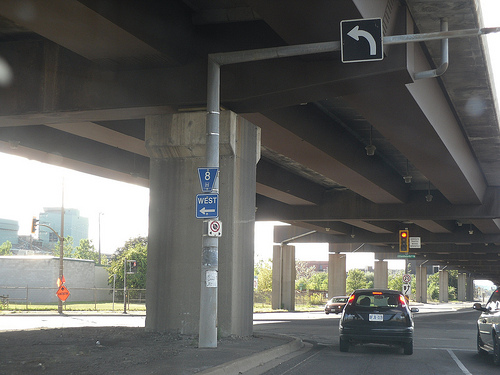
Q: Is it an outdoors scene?
A: Yes, it is outdoors.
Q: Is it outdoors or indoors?
A: It is outdoors.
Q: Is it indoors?
A: No, it is outdoors.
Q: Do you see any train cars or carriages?
A: No, there are no train cars or carriages.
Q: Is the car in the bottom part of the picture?
A: Yes, the car is in the bottom of the image.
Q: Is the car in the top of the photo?
A: No, the car is in the bottom of the image.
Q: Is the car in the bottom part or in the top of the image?
A: The car is in the bottom of the image.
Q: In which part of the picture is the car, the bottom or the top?
A: The car is in the bottom of the image.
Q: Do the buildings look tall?
A: Yes, the buildings are tall.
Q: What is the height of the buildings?
A: The buildings are tall.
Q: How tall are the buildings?
A: The buildings are tall.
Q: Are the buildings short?
A: No, the buildings are tall.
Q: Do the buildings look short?
A: No, the buildings are tall.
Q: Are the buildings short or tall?
A: The buildings are tall.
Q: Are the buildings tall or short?
A: The buildings are tall.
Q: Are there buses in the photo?
A: No, there are no buses.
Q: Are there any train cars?
A: No, there are no train cars.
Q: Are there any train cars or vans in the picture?
A: No, there are no train cars or vans.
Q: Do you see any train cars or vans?
A: No, there are no train cars or vans.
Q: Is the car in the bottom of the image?
A: Yes, the car is in the bottom of the image.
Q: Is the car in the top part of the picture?
A: No, the car is in the bottom of the image.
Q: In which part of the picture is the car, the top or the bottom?
A: The car is in the bottom of the image.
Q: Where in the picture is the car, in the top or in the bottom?
A: The car is in the bottom of the image.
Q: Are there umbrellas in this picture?
A: No, there are no umbrellas.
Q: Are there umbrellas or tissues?
A: No, there are no umbrellas or tissues.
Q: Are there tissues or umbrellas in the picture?
A: No, there are no umbrellas or tissues.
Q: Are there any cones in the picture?
A: No, there are no cones.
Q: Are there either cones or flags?
A: No, there are no cones or flags.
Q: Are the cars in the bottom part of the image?
A: Yes, the cars are in the bottom of the image.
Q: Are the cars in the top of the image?
A: No, the cars are in the bottom of the image.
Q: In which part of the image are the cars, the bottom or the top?
A: The cars are in the bottom of the image.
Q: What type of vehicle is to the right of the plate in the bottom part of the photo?
A: The vehicles are cars.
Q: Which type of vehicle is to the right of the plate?
A: The vehicles are cars.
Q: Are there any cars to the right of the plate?
A: Yes, there are cars to the right of the plate.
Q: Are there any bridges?
A: Yes, there is a bridge.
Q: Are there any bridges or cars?
A: Yes, there is a bridge.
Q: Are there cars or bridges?
A: Yes, there is a bridge.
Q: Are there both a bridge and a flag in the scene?
A: No, there is a bridge but no flags.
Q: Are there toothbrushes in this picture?
A: No, there are no toothbrushes.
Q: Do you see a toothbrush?
A: No, there are no toothbrushes.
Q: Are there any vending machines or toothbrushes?
A: No, there are no toothbrushes or vending machines.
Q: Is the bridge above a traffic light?
A: Yes, the bridge is above a traffic light.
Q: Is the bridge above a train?
A: No, the bridge is above a traffic light.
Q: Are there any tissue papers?
A: No, there are no tissue papers.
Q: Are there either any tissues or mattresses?
A: No, there are no tissues or mattresses.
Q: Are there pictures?
A: No, there are no pictures.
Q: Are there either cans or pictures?
A: No, there are no pictures or cans.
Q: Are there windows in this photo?
A: Yes, there is a window.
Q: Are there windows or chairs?
A: Yes, there is a window.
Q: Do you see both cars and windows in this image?
A: Yes, there are both a window and a car.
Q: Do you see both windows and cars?
A: Yes, there are both a window and a car.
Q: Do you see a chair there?
A: No, there are no chairs.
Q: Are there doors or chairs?
A: No, there are no chairs or doors.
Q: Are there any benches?
A: No, there are no benches.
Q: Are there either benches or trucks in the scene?
A: No, there are no benches or trucks.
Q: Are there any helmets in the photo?
A: No, there are no helmets.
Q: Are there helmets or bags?
A: No, there are no helmets or bags.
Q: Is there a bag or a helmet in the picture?
A: No, there are no helmets or bags.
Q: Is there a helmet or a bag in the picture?
A: No, there are no helmets or bags.